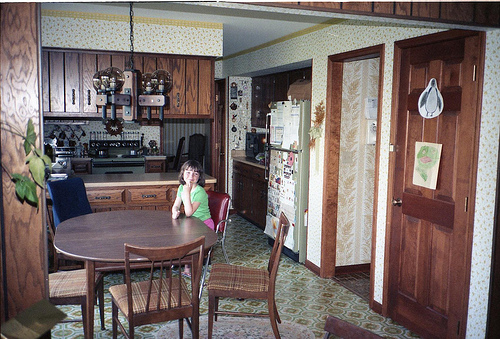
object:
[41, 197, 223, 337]
table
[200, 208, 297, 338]
chair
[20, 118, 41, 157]
leaves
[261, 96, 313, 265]
refrigerator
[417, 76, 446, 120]
drawing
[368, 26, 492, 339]
door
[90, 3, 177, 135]
light fixture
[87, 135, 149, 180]
stove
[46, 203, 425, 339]
flooring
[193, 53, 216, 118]
cabinets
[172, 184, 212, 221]
top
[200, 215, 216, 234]
shorts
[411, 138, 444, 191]
drawing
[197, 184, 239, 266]
chair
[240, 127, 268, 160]
microwave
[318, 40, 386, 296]
doorframe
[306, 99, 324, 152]
things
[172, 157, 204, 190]
head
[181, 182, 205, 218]
left arm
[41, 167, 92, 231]
chair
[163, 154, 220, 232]
girl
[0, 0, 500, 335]
kitchen